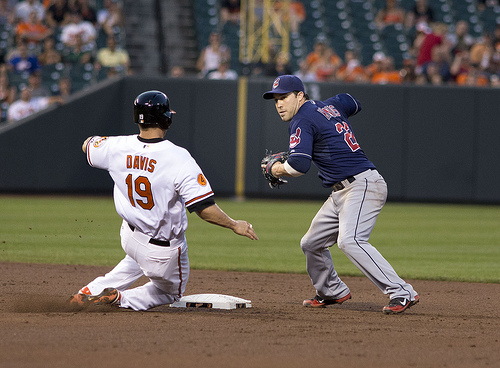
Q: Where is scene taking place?
A: Baseball field.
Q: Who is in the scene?
A: A lot of people.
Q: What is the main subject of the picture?
A: The play happening on the field.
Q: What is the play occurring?
A: One man is sliding into base and other is trying to tag him out.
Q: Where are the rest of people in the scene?
A: In the bleacher.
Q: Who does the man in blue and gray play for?
A: Cleveland Indians.